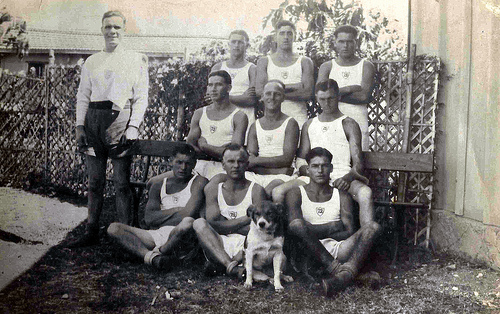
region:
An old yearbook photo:
[50, 4, 422, 298]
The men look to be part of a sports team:
[130, 22, 414, 276]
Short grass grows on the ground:
[165, 267, 420, 312]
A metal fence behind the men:
[4, 56, 432, 238]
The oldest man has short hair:
[104, 9, 129, 26]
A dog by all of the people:
[237, 199, 297, 290]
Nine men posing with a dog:
[152, 19, 393, 271]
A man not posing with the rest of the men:
[71, 6, 168, 232]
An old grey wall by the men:
[422, 3, 499, 188]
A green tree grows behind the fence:
[266, 0, 393, 67]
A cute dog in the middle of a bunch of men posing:
[234, 195, 299, 295]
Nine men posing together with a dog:
[162, 16, 405, 281]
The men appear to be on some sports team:
[167, 26, 392, 281]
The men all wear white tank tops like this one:
[305, 111, 367, 178]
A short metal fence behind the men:
[0, 56, 440, 242]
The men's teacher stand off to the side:
[72, 5, 159, 240]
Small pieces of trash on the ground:
[445, 253, 492, 300]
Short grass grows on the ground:
[150, 280, 243, 310]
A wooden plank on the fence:
[122, 123, 450, 178]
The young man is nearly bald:
[262, 79, 290, 94]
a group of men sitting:
[55, 6, 400, 300]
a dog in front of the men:
[233, 194, 293, 296]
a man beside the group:
[72, 6, 150, 243]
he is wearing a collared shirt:
[69, 40, 153, 130]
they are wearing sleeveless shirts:
[130, 13, 378, 275]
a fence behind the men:
[0, 38, 451, 255]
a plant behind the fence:
[241, 0, 423, 55]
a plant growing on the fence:
[147, 44, 212, 104]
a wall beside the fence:
[403, 0, 495, 272]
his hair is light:
[96, 6, 134, 21]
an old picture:
[9, 0, 494, 302]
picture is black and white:
[1, 4, 498, 311]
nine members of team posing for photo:
[111, 21, 408, 291]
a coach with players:
[66, 5, 401, 295]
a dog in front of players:
[151, 135, 372, 301]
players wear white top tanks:
[119, 21, 392, 312]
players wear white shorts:
[134, 13, 417, 294]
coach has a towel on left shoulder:
[71, 3, 154, 232]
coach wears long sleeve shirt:
[57, 5, 159, 238]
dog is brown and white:
[237, 190, 295, 296]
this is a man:
[283, 150, 376, 280]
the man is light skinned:
[255, 101, 289, 121]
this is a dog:
[246, 205, 283, 282]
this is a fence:
[400, 65, 426, 200]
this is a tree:
[296, 7, 352, 26]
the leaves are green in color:
[320, 3, 327, 28]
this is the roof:
[46, 30, 86, 47]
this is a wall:
[453, 38, 498, 258]